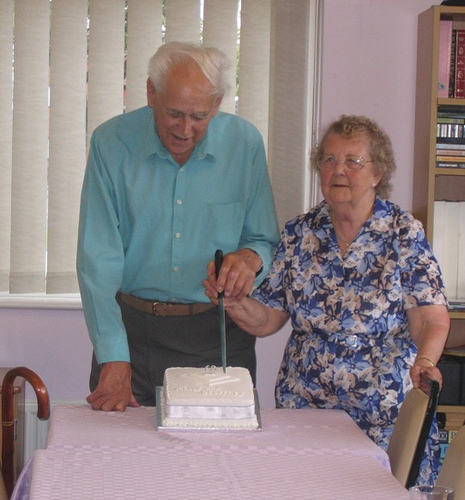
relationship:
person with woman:
[75, 41, 282, 413] [220, 115, 451, 492]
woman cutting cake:
[220, 115, 451, 492] [158, 350, 257, 430]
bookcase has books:
[418, 5, 463, 358] [440, 7, 455, 101]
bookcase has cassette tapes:
[418, 5, 463, 358] [435, 142, 463, 169]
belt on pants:
[117, 289, 220, 319] [119, 300, 264, 408]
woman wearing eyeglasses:
[220, 115, 451, 492] [307, 153, 367, 171]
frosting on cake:
[198, 381, 203, 382] [154, 362, 262, 429]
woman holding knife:
[202, 115, 458, 499] [212, 254, 227, 370]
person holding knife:
[75, 41, 282, 413] [212, 254, 227, 370]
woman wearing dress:
[202, 115, 458, 499] [253, 198, 449, 419]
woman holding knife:
[220, 115, 451, 492] [210, 251, 228, 371]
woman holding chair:
[220, 115, 451, 492] [383, 377, 440, 488]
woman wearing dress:
[220, 115, 451, 492] [251, 202, 452, 497]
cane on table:
[6, 366, 46, 484] [31, 406, 423, 493]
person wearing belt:
[75, 41, 282, 413] [116, 291, 220, 316]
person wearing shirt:
[75, 41, 282, 413] [87, 103, 279, 310]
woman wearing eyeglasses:
[202, 115, 458, 499] [315, 153, 376, 173]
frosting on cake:
[198, 386, 211, 399] [153, 367, 261, 436]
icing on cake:
[224, 394, 234, 402] [154, 362, 262, 429]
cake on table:
[154, 362, 262, 429] [33, 404, 408, 497]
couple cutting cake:
[75, 43, 447, 487] [153, 367, 261, 436]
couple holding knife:
[75, 43, 447, 487] [209, 251, 229, 365]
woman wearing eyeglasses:
[220, 115, 451, 492] [313, 154, 362, 170]